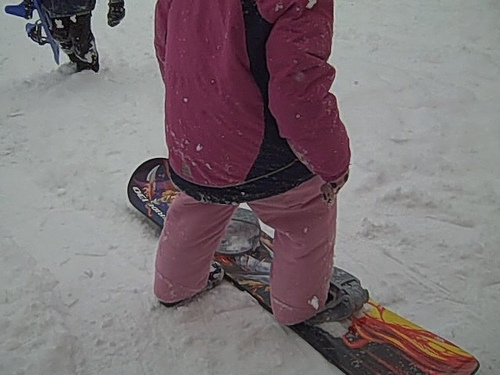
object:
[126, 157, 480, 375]
skate board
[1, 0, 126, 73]
person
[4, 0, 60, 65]
blue snowboard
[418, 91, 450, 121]
ground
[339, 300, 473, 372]
design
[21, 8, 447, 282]
field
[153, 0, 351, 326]
boy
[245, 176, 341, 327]
leg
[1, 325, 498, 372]
snow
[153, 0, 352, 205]
coat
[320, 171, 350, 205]
hand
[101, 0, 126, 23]
leg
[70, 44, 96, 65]
snow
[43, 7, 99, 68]
dark pants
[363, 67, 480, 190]
snow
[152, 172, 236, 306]
leg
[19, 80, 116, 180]
ground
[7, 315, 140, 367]
ground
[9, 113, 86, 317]
snow